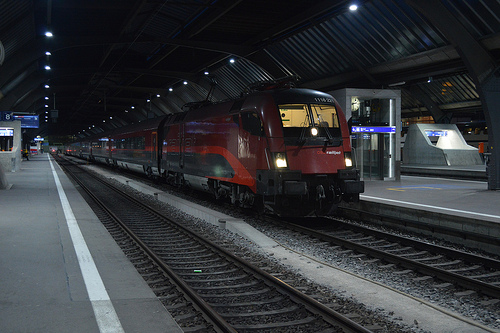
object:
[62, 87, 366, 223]
train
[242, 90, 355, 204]
cabin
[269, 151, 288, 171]
headlights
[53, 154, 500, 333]
tracks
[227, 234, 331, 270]
gravel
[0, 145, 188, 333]
walkway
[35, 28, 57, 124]
lights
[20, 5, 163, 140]
roof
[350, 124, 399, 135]
sign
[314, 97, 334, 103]
numbers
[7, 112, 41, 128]
sign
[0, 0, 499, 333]
station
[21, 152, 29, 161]
man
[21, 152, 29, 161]
chair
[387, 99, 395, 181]
pole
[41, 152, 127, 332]
line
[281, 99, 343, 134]
windows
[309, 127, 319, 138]
light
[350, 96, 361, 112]
clock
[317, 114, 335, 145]
wipers